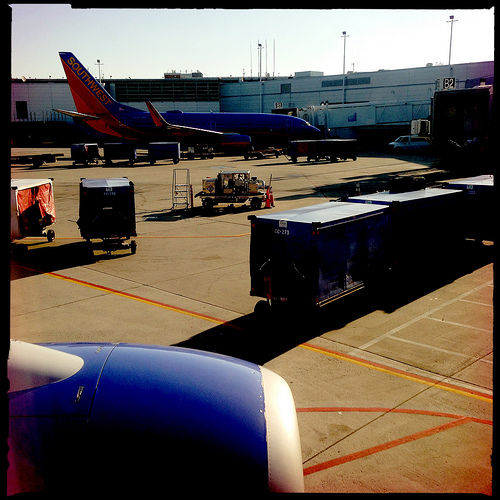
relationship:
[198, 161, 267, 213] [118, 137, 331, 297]
tractor on road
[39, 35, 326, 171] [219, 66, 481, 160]
plane by airport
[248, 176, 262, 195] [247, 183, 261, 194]
person wearing orange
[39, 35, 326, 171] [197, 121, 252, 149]
plane has engine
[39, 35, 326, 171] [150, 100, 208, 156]
plane has wing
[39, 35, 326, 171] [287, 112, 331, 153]
plane has nose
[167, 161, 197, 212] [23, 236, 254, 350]
ladder on ground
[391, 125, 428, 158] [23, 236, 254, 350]
van on ground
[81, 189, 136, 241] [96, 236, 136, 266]
truck as wheels